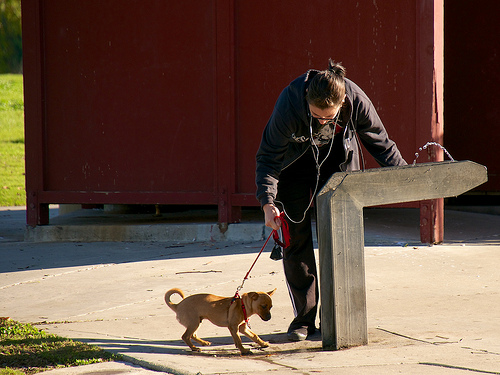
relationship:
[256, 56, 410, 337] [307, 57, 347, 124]
woman has head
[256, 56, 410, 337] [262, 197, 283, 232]
woman has hand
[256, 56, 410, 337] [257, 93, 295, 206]
woman has arm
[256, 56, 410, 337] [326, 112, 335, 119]
woman has eye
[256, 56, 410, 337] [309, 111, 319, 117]
woman has eye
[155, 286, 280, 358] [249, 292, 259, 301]
dog has ear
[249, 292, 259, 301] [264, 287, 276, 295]
ear has ear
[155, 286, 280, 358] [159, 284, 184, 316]
dog has tail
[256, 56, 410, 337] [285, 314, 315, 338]
woman has foot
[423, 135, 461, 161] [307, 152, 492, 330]
water spurting from waterfountain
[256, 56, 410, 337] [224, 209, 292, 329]
woman holding leash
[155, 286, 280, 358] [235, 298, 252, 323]
dog wearing collar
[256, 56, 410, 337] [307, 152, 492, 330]
woman standing by waterfountain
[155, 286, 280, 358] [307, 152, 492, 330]
dog standing by waterfountain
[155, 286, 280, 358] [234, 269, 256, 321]
dog wearing harness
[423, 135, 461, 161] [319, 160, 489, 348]
water above fountain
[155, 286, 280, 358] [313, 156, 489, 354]
dog standing next to post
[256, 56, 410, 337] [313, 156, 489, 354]
woman standing next to post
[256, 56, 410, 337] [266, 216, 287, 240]
woman holding tie